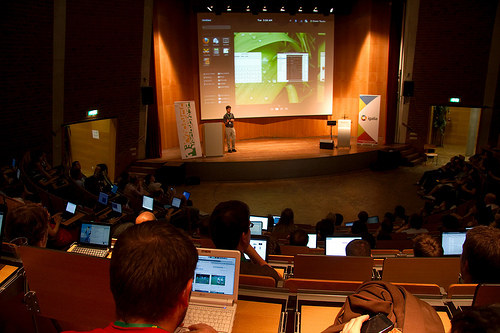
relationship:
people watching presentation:
[117, 171, 163, 194] [285, 70, 328, 119]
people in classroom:
[117, 171, 163, 194] [3, 142, 500, 333]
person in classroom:
[205, 199, 285, 283] [3, 142, 500, 333]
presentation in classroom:
[285, 70, 328, 119] [3, 142, 500, 333]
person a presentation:
[205, 199, 285, 283] [285, 70, 328, 119]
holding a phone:
[432, 175, 445, 188] [425, 178, 448, 185]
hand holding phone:
[436, 178, 453, 186] [425, 178, 448, 185]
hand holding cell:
[436, 178, 453, 186] [427, 179, 444, 189]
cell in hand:
[427, 179, 444, 189] [436, 178, 453, 186]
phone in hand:
[425, 178, 448, 185] [436, 178, 453, 186]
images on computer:
[195, 263, 233, 289] [199, 237, 255, 301]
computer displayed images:
[199, 237, 255, 301] [195, 263, 233, 289]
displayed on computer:
[203, 262, 222, 299] [199, 237, 255, 301]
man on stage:
[218, 104, 241, 154] [219, 129, 240, 163]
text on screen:
[234, 63, 262, 87] [214, 12, 344, 109]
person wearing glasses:
[222, 219, 269, 271] [245, 219, 255, 230]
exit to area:
[80, 105, 131, 136] [93, 136, 147, 174]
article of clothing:
[222, 131, 244, 153] [228, 124, 235, 156]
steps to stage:
[391, 147, 423, 176] [219, 129, 240, 163]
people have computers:
[117, 171, 163, 194] [310, 233, 369, 256]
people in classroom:
[117, 171, 163, 194] [3, 165, 476, 198]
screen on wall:
[214, 12, 344, 109] [96, 40, 255, 121]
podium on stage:
[193, 116, 236, 160] [219, 129, 240, 163]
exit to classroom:
[80, 105, 131, 136] [3, 165, 476, 198]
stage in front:
[219, 129, 240, 163] [240, 179, 301, 223]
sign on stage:
[344, 93, 381, 153] [219, 129, 240, 163]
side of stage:
[141, 74, 197, 175] [219, 129, 240, 163]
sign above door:
[344, 93, 381, 153] [441, 97, 480, 142]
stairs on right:
[420, 190, 444, 233] [95, 211, 152, 234]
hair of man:
[228, 101, 229, 109] [218, 104, 241, 154]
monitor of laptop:
[167, 249, 241, 332] [196, 243, 228, 328]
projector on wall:
[207, 7, 332, 17] [96, 40, 255, 121]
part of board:
[332, 122, 357, 153] [333, 110, 354, 167]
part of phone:
[332, 122, 357, 153] [425, 178, 448, 185]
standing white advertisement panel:
[178, 107, 209, 178] [167, 95, 207, 163]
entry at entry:
[53, 111, 126, 186] [53, 126, 119, 186]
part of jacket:
[332, 122, 357, 153] [323, 280, 413, 314]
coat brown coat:
[316, 275, 449, 333] [339, 285, 442, 332]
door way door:
[436, 97, 480, 151] [436, 97, 480, 151]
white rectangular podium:
[205, 135, 214, 161] [193, 116, 236, 160]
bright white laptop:
[199, 237, 255, 301] [196, 243, 228, 328]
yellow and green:
[180, 117, 191, 142] [185, 104, 201, 138]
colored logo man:
[351, 92, 382, 131] [215, 101, 241, 154]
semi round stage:
[147, 146, 413, 179] [219, 129, 240, 163]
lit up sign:
[451, 97, 462, 104] [344, 93, 381, 153]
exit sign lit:
[80, 105, 131, 136] [451, 97, 462, 104]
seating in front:
[262, 207, 420, 240] [240, 179, 301, 223]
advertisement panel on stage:
[173, 100, 202, 161] [125, 138, 401, 179]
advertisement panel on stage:
[355, 92, 381, 141] [125, 138, 401, 179]